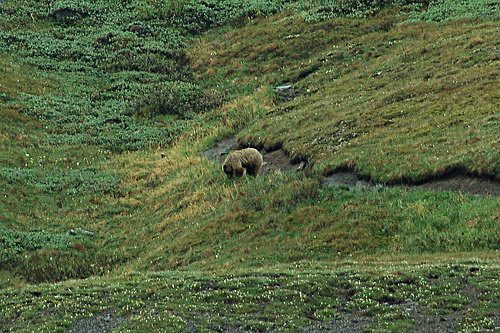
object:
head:
[222, 163, 231, 180]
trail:
[211, 134, 484, 196]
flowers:
[457, 318, 484, 328]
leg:
[243, 167, 263, 179]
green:
[132, 90, 152, 107]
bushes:
[55, 41, 191, 143]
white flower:
[363, 286, 386, 299]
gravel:
[325, 310, 382, 330]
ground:
[0, 0, 499, 330]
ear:
[220, 164, 234, 172]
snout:
[216, 169, 242, 180]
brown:
[237, 150, 262, 166]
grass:
[0, 0, 500, 333]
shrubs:
[104, 73, 498, 128]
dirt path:
[209, 142, 500, 191]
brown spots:
[221, 27, 275, 59]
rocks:
[398, 308, 463, 329]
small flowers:
[349, 264, 415, 316]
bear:
[220, 146, 263, 178]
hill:
[255, 14, 498, 268]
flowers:
[348, 274, 397, 315]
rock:
[273, 75, 294, 98]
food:
[225, 177, 234, 181]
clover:
[21, 143, 81, 173]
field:
[0, 1, 500, 332]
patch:
[246, 132, 498, 201]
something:
[272, 79, 297, 97]